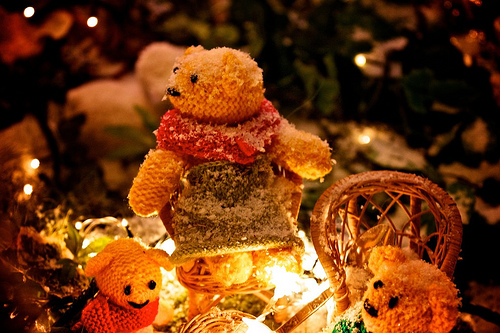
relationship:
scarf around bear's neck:
[72, 292, 165, 328] [95, 289, 159, 312]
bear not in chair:
[60, 43, 185, 191] [317, 166, 469, 261]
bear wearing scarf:
[125, 44, 339, 285] [156, 100, 286, 163]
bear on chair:
[89, 53, 318, 293] [312, 139, 474, 306]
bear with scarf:
[125, 44, 339, 285] [139, 104, 296, 170]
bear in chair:
[125, 44, 339, 285] [308, 161, 468, 328]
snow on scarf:
[154, 116, 331, 176] [153, 107, 302, 159]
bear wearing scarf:
[76, 239, 176, 332] [76, 295, 162, 332]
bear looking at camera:
[76, 239, 176, 332] [9, 11, 493, 331]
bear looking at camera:
[326, 243, 463, 331] [9, 11, 493, 331]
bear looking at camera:
[125, 44, 339, 285] [9, 11, 493, 331]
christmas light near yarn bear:
[272, 258, 318, 305] [127, 48, 342, 280]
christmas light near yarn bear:
[272, 258, 318, 305] [339, 244, 470, 331]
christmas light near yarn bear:
[272, 258, 318, 305] [78, 232, 175, 332]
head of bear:
[159, 36, 277, 120] [60, 43, 185, 191]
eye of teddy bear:
[186, 71, 203, 88] [124, 38, 355, 298]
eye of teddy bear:
[171, 66, 178, 73] [127, 43, 336, 321]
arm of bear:
[128, 147, 183, 217] [60, 43, 185, 191]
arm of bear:
[279, 124, 337, 174] [60, 43, 185, 191]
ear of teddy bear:
[81, 245, 116, 277] [66, 231, 173, 331]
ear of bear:
[148, 246, 171, 272] [76, 239, 176, 332]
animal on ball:
[119, 48, 302, 273] [168, 44, 292, 117]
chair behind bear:
[308, 166, 463, 310] [326, 243, 463, 331]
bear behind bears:
[1, 43, 197, 207] [44, 45, 472, 331]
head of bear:
[159, 44, 266, 123] [125, 44, 339, 285]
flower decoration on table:
[7, 181, 87, 331] [2, 179, 499, 331]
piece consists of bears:
[19, 52, 439, 332] [44, 45, 472, 331]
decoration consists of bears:
[126, 42, 333, 294] [44, 45, 472, 331]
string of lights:
[17, 8, 427, 70] [3, 2, 499, 84]